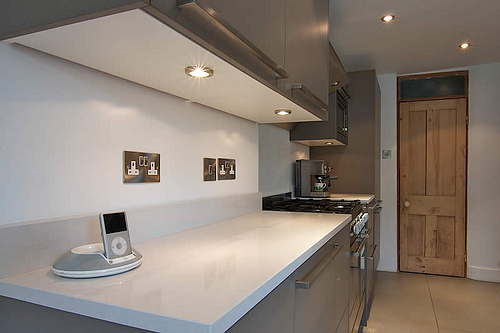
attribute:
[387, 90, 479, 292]
door — brown, wooden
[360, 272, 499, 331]
floor — tan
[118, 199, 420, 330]
counter — long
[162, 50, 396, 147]
light — on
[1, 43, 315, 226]
wall — white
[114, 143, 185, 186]
plug — electric 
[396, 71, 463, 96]
window — small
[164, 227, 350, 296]
countertop — white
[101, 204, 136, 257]
ipod — gray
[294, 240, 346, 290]
handle — silver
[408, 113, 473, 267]
door — brown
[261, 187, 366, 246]
stove — gas 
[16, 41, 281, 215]
wall — smooth, white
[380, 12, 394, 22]
light — recessed 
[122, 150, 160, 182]
picture — small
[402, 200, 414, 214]
knob —  white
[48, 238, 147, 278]
charging station — white, gray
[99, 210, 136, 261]
ipod — silver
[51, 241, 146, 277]
trackpad — white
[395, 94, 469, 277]
entry door — wood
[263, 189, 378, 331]
stove — silver 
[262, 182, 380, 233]
kitchen stove — Gas burning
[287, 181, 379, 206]
counter — small